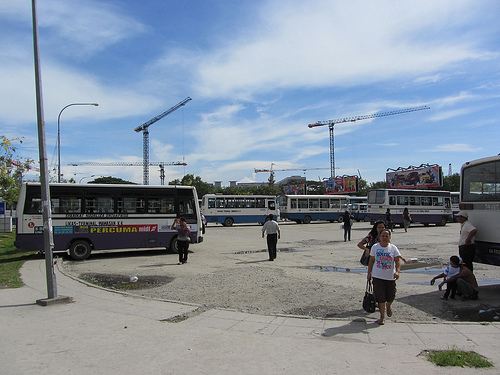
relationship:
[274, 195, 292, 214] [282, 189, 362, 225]
window on bus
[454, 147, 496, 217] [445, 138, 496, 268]
window on bus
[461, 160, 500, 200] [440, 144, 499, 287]
window on bus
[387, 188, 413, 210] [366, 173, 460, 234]
window on bus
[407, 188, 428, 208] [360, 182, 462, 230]
window on bus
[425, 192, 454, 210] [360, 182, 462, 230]
window on bus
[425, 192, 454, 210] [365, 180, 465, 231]
window on bus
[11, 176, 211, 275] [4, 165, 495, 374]
bus parked in lot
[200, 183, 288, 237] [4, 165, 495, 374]
bus parked in lot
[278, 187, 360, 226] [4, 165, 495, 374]
bus parked in lot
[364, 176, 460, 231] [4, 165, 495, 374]
bus parked in lot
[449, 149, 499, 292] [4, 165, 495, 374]
bus parked in lot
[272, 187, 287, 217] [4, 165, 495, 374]
bus parked in lot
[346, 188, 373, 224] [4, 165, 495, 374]
bus parked in lot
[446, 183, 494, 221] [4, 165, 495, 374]
bus parked in lot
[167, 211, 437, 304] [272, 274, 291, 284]
people in lot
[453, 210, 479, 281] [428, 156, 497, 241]
man behind bus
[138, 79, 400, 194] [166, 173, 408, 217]
cranes above busses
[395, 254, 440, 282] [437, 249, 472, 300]
water by squaters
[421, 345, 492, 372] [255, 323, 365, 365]
patch in sidewalk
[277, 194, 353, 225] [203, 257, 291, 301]
bus in lot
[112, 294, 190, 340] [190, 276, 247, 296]
sidewalk along lot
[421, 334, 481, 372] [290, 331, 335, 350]
patch on sidewalk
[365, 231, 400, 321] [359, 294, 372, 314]
person carrying purse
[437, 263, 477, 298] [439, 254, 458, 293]
boy kneeling with child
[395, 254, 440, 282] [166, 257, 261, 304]
water in lot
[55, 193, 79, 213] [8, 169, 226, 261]
window on bus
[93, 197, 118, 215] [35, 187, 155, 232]
window on bus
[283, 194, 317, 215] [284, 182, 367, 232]
window on bus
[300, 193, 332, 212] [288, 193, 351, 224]
window on bus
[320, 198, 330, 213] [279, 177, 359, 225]
window on bus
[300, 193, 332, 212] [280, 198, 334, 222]
window on bus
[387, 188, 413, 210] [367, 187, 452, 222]
window on bus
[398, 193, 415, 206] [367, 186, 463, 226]
window on bus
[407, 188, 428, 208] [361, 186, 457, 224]
window on bus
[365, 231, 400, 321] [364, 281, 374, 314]
person carrying purse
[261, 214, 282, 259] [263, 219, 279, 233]
man wearing shirt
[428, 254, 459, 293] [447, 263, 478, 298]
child behind boy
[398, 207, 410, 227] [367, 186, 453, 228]
person near bus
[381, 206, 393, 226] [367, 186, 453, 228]
person near bus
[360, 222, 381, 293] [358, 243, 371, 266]
woman holding purse